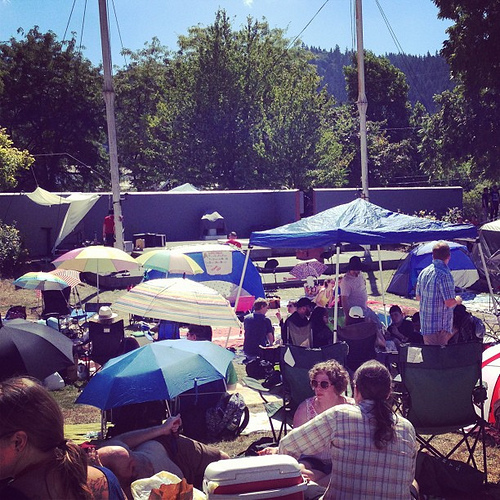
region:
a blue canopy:
[263, 198, 499, 260]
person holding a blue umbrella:
[76, 332, 253, 432]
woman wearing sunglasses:
[304, 370, 336, 395]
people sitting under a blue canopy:
[253, 295, 464, 353]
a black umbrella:
[3, 315, 83, 376]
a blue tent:
[193, 235, 278, 299]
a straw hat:
[91, 299, 118, 322]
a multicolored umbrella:
[46, 241, 149, 275]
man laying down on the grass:
[85, 421, 261, 476]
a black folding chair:
[406, 345, 495, 476]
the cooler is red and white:
[198, 450, 329, 498]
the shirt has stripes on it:
[313, 397, 425, 487]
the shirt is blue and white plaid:
[416, 262, 464, 315]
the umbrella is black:
[1, 310, 78, 385]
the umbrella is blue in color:
[79, 331, 247, 423]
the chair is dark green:
[392, 338, 498, 450]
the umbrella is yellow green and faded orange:
[138, 242, 223, 283]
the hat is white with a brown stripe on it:
[83, 300, 142, 331]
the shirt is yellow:
[312, 288, 345, 311]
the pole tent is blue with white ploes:
[221, 192, 499, 367]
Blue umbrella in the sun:
[67, 335, 237, 417]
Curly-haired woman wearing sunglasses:
[289, 354, 356, 430]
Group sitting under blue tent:
[220, 190, 492, 399]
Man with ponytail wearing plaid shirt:
[270, 357, 418, 499]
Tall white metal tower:
[95, 0, 126, 264]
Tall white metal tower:
[352, 0, 375, 246]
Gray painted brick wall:
[0, 187, 469, 257]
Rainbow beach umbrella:
[50, 242, 142, 314]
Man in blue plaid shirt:
[413, 239, 460, 354]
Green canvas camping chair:
[391, 342, 491, 497]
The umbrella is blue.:
[62, 320, 257, 421]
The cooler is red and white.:
[200, 440, 312, 498]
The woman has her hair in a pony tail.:
[0, 378, 121, 495]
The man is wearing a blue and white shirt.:
[385, 220, 466, 366]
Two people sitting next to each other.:
[276, 338, 421, 488]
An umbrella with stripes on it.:
[107, 267, 242, 337]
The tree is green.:
[130, 6, 341, 181]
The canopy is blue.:
[220, 171, 486, 336]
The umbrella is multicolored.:
[46, 235, 147, 311]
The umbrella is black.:
[0, 308, 93, 392]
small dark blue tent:
[230, 154, 485, 384]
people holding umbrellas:
[37, 228, 282, 481]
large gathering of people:
[27, 231, 454, 485]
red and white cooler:
[196, 445, 327, 495]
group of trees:
[33, 11, 465, 223]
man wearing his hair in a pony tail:
[316, 347, 456, 486]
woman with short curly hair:
[285, 340, 351, 438]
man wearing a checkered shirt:
[401, 235, 475, 353]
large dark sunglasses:
[305, 362, 387, 453]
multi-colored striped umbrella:
[121, 269, 280, 336]